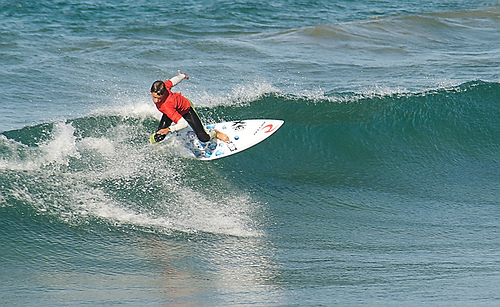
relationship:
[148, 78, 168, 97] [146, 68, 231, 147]
hair belonging to boy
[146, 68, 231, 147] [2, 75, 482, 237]
boy riding wave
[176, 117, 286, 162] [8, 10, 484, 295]
surfboard riding on water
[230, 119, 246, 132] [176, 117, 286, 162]
sticker stuck on surfboard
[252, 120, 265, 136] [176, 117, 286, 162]
logo painted on surfboard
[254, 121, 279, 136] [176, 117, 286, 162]
logo painted on surfboard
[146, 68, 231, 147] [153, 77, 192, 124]
boy wearing shirt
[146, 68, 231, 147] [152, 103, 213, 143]
boy wearing wetsuit pants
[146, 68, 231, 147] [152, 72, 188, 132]
boy wearing shirt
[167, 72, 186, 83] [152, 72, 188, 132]
sleeve attached to shirt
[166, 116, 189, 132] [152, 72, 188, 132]
sleeve attached to shirt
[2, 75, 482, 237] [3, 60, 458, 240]
wave creating spray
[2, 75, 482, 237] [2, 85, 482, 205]
wave creating swell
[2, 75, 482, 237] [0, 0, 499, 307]
wave created in ocean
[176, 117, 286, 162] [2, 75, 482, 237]
surfboard coming out of wave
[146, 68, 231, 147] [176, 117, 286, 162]
boy riding surfboard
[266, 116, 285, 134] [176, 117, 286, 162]
nose belonging to surfboard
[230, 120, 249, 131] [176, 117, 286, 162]
sticker painted on surfboard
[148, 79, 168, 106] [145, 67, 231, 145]
head belonging to boy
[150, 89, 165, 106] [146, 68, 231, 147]
face belonging to boy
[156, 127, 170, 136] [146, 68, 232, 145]
left hand belonging to person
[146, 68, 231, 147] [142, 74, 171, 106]
boy has head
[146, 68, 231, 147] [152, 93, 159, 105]
boy has nose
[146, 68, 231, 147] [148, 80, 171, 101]
boy has hair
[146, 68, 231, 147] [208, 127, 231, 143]
boy has foot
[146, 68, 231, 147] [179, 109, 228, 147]
boy has leg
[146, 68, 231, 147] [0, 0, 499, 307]
boy in ocean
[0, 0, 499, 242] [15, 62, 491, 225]
wave in ocean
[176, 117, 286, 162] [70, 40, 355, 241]
surfboard in water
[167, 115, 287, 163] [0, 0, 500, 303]
surfboard in water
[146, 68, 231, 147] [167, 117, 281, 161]
boy on surfboard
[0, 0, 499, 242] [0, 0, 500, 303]
wave in water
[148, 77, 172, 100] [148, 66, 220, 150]
hair on surfer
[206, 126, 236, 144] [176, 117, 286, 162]
foot on surfboard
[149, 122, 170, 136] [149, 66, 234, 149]
left hand on surfer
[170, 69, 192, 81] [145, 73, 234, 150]
right hand on surfer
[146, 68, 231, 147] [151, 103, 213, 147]
boy wearing pants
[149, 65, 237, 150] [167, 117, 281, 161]
boy on surfboard